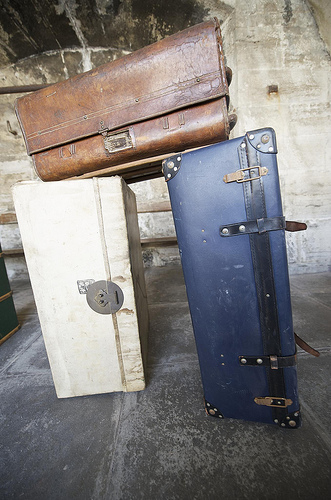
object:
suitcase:
[161, 127, 302, 429]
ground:
[2, 429, 325, 498]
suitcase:
[11, 175, 150, 399]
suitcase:
[13, 18, 237, 184]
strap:
[219, 216, 285, 237]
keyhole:
[99, 300, 104, 305]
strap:
[285, 221, 307, 232]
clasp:
[86, 280, 124, 314]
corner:
[246, 127, 277, 155]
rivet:
[222, 228, 228, 234]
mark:
[233, 264, 244, 268]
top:
[163, 127, 276, 163]